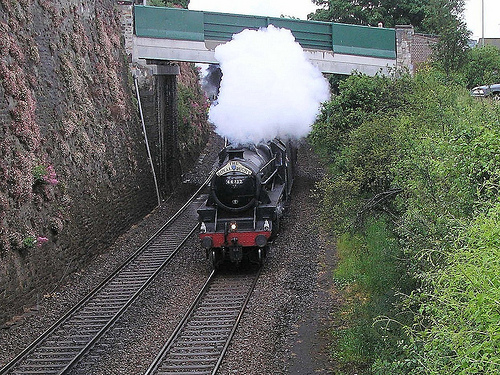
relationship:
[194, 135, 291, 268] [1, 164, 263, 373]
locomotive on rails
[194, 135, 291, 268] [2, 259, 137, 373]
locomotive on tracks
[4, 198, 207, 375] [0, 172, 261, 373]
tie on track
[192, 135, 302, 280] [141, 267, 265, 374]
locomotive on a track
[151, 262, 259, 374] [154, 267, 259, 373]
tie on a track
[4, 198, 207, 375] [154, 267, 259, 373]
tie on a track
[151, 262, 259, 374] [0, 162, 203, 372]
tie on a track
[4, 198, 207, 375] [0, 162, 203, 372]
tie on a track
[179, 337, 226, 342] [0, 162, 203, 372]
tie on a track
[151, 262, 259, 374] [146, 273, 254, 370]
tie on a track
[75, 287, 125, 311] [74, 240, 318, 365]
tie of track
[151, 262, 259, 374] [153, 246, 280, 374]
tie of track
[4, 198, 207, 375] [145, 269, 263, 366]
tie of track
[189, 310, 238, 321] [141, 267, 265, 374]
tie of track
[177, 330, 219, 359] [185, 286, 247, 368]
cross tie of track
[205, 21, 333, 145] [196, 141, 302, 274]
cloud from train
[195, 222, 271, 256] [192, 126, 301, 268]
bumper on train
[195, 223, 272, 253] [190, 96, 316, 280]
bumper on train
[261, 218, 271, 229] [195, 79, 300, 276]
letter a on front right side of train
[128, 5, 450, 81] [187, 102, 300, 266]
overpass above train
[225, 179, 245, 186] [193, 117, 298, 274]
numbers on train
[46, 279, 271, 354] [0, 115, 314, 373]
gravel in between tracks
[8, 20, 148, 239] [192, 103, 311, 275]
rock wall on side of train